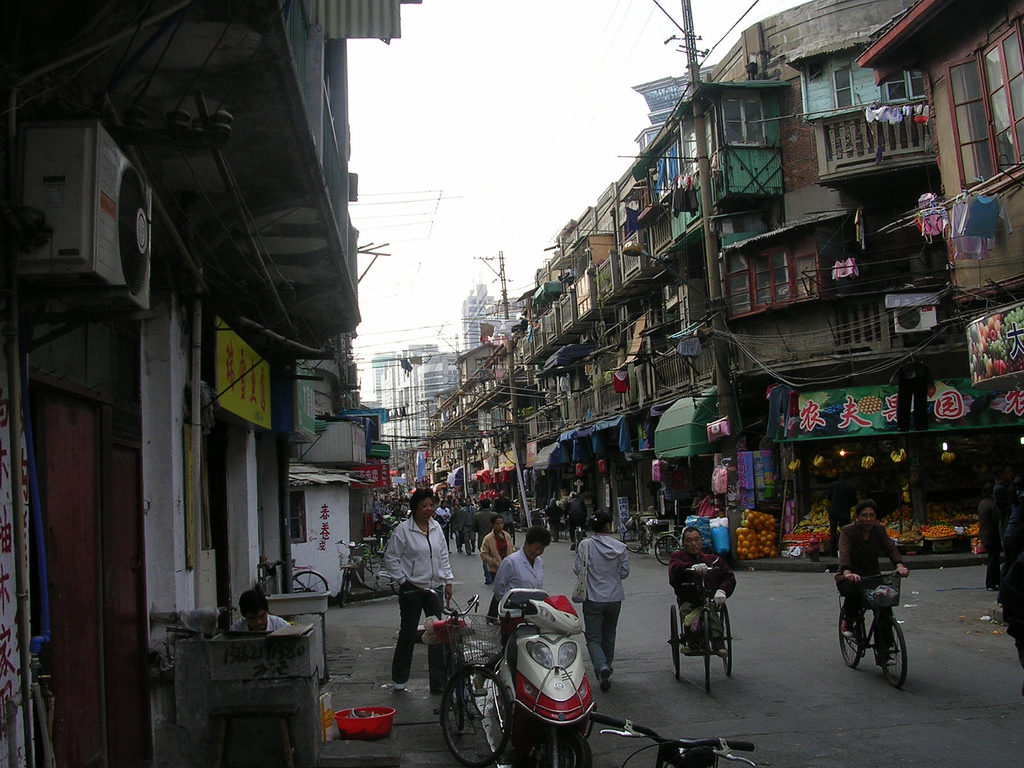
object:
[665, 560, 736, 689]
cart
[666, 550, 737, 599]
sweatshirt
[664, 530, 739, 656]
man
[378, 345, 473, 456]
wall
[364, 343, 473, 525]
building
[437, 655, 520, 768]
tire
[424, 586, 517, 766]
bike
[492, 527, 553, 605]
people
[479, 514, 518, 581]
people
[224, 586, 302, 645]
people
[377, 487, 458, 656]
people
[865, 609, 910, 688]
tire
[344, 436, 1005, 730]
street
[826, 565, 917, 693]
bike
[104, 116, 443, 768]
left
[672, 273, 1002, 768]
right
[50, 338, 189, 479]
wall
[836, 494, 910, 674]
people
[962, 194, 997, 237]
clothes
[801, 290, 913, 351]
window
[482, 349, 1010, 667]
background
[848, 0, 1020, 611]
building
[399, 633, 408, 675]
black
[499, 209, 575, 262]
cloudy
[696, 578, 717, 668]
wheels